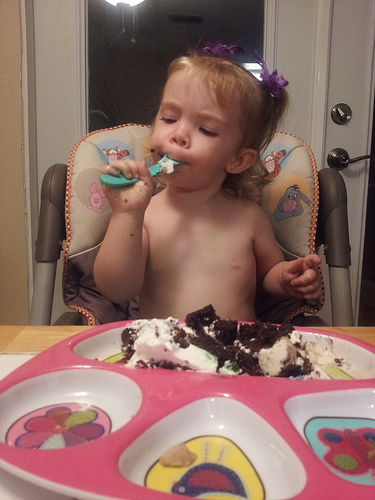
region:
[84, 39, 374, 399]
a girl sitting in a high chair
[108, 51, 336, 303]
a young girl sitting in high chair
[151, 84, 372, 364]
a child sitting in high chiar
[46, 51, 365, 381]
a young child sitting in high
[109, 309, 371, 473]
a cake on a plate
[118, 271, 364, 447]
a plate with cake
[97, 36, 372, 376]
a child eatting a cake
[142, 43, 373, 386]
a girl eatting a cake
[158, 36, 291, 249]
a child with blonde hair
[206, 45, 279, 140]
a girl with blonde hair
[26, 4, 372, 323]
white door with window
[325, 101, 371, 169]
door lock and handle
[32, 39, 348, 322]
shirtless child in stroller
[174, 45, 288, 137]
purple bows in hair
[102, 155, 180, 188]
green utensil in mouth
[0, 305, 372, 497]
cake in child's plate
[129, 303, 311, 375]
crumbled up chocolate cake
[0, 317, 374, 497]
pink and white plate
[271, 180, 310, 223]
cartoon animal on cushion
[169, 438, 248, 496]
bird cartoon on plate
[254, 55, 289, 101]
a purple hair bow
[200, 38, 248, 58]
a purple hair bow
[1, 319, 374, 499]
a child's colorful pink plate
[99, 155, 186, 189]
a child's blue spoon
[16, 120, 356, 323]
a child's high chair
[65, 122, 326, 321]
a Winnie the Pooh plush seat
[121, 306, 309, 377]
a mashed piece of cake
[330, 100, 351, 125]
a silver door lock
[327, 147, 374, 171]
a silver door handle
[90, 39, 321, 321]
a child eating cake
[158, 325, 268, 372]
chocolate cake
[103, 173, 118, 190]
handle on the utensil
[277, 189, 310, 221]
eeyore of the baby seat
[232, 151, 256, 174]
the childs ear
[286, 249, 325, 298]
the childs hand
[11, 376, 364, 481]
a childs plate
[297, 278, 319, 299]
the childs fingers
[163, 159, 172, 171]
frosting on the utensil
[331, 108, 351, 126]
lock on the door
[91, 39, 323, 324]
this is a person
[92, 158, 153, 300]
this is a person's hand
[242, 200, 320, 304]
this is a person's hand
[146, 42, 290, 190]
this is a person's head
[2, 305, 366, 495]
this is a plate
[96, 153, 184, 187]
this is a spoon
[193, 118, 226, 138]
this is a person's eye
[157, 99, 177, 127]
this is a person's eye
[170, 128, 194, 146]
this is a person's nose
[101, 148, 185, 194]
this is a green spoon